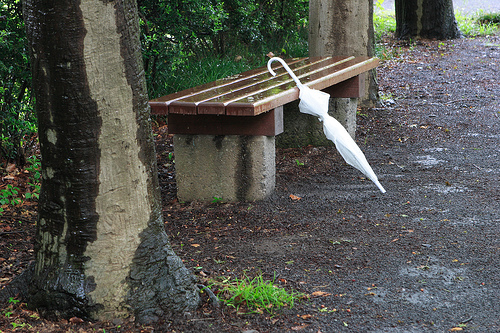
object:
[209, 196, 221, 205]
growth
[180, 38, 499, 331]
walkway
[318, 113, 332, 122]
strap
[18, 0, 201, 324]
bark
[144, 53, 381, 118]
board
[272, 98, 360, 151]
cement support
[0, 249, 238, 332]
tree base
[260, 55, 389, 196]
umbrella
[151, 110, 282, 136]
piece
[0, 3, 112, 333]
wet spot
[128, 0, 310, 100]
grass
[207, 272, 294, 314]
grass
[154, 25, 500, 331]
ground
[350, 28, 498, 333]
soil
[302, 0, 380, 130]
trees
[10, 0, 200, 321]
tree trunk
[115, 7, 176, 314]
black mark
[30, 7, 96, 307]
black mark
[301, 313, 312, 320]
leaves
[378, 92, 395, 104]
leaves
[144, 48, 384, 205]
bench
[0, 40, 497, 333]
wet ground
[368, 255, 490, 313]
spot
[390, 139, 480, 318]
puddles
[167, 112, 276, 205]
base